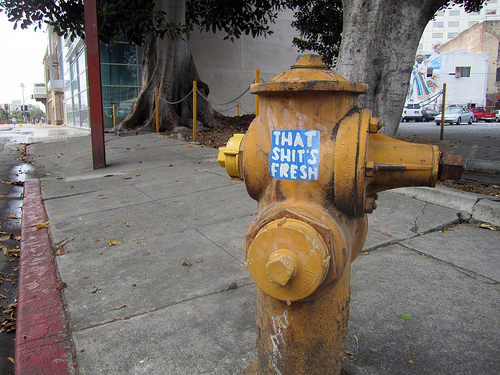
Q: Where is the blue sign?
A: On the hydrant.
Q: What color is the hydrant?
A: Yellow.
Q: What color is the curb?
A: Red.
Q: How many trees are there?
A: Two.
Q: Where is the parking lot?
A: Behind the trees.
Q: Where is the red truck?
A: In the parking lot.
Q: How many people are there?
A: None.